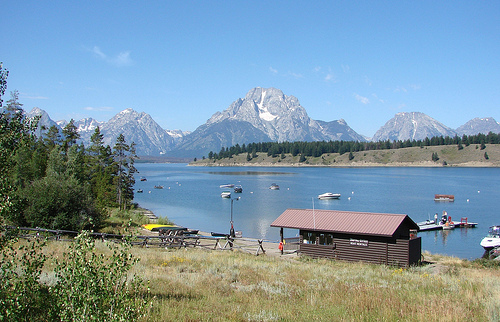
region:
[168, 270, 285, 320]
The grass is the color yellow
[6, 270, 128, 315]
The leaves are short and green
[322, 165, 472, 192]
The lake water is calm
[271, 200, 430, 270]
The store on the lake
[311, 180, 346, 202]
The boat on the lake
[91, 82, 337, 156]
The mountains are majestic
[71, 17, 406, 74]
The sky is clear and blue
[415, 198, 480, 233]
The doc in the water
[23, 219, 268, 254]
The gate is made of metal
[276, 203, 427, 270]
The building is the color brown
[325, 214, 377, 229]
Roof of a structure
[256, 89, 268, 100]
The summit of the mountain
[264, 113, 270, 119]
Snow on the mountain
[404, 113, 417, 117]
A dome shaped mountain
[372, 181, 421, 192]
A blue body of water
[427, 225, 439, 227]
The surface of a pier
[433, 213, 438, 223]
A person standing on the pier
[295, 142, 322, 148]
A forest in the background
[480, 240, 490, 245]
A boat near the shore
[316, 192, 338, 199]
A boat in the water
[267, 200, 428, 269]
brown building by the lake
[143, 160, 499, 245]
boats in the lake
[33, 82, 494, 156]
range of mountains behind lake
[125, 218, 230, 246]
picnic tables on shoreline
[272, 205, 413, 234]
brown roof of the building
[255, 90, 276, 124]
snow on the mountainside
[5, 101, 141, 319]
trees along foreground shoreline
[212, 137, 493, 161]
trees on background shoreline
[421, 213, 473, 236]
dock in the water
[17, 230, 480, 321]
patchy grass on the shoreline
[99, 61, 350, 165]
mountains in the background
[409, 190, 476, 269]
people on the deck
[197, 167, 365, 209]
boats on the water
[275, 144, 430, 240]
the water is blue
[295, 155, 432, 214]
the water is calm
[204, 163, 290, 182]
a patch of shiny water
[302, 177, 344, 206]
the boat is white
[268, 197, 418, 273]
the building is brown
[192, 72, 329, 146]
the mountain has snow on it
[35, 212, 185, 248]
the benches are empty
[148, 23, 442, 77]
The sky is the color blue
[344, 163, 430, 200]
The lake water is calm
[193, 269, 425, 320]
The grass is the color yellow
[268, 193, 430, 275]
The store on the ground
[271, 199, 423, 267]
The store is the color brown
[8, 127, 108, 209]
The trees are the color green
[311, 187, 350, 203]
The boat on the water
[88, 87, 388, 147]
The mountains are the color grey